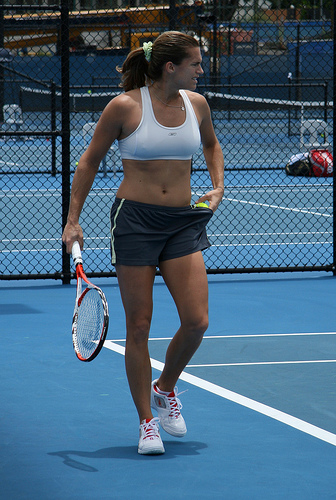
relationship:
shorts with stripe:
[100, 189, 223, 272] [111, 197, 126, 264]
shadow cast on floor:
[47, 441, 208, 472] [0, 102, 332, 499]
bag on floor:
[309, 148, 333, 175] [0, 102, 332, 489]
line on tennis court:
[92, 331, 336, 499] [0, 112, 334, 497]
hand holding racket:
[59, 218, 89, 258] [66, 248, 135, 362]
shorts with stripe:
[110, 197, 211, 266] [106, 197, 123, 267]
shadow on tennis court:
[46, 439, 207, 471] [3, 269, 334, 498]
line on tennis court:
[89, 337, 333, 449] [2, 3, 335, 498]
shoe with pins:
[149, 376, 189, 436] [136, 411, 159, 439]